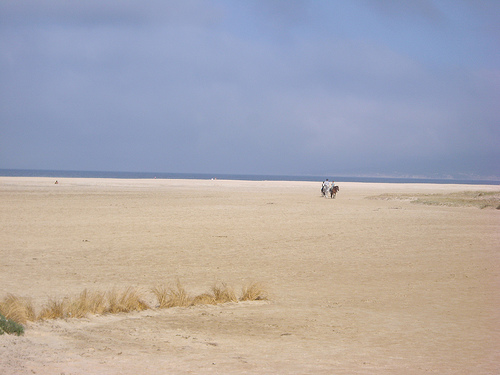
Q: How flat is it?
A: Very flat.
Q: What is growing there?
A: Grass.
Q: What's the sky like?
A: Clear.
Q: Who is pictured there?
A: 2 people.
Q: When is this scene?
A: Afternoon.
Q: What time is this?
A: Afternoon.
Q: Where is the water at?
A: Far.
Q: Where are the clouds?
A: Sky.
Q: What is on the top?
A: Sky.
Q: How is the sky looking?
A: Clear.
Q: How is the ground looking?
A: Dry.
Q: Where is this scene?
A: Beach.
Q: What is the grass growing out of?
A: Sand.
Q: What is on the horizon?
A: Ocean.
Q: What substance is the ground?
A: Sand.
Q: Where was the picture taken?
A: At a beach.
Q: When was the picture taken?
A: Daytime.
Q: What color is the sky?
A: Blue.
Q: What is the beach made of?
A: Sand.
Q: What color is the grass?
A: Brown.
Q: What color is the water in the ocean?
A: Blue.